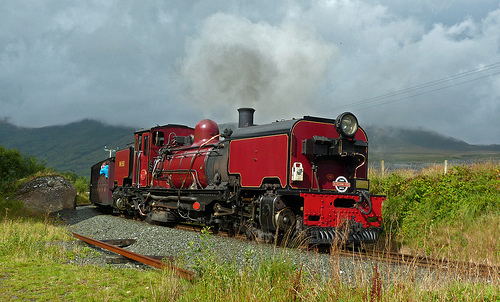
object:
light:
[328, 107, 366, 145]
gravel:
[110, 226, 263, 276]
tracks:
[158, 212, 498, 278]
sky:
[1, 0, 498, 152]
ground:
[37, 224, 254, 271]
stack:
[178, 227, 257, 270]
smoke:
[174, 15, 289, 115]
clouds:
[324, 7, 499, 87]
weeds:
[216, 223, 490, 300]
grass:
[398, 162, 498, 252]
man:
[91, 157, 111, 185]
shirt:
[96, 165, 113, 178]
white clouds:
[300, 18, 472, 77]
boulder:
[2, 165, 98, 225]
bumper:
[287, 207, 398, 258]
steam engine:
[52, 61, 433, 259]